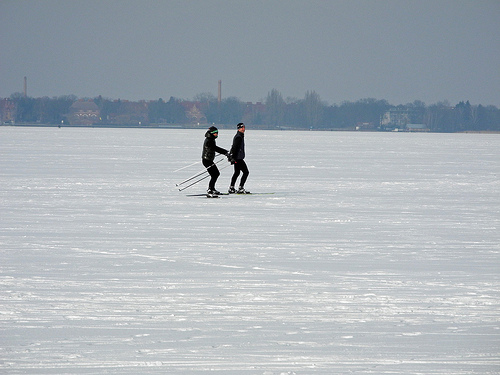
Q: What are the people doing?
A: Skiing.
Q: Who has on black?
A: People skiing.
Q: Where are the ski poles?
A: In people's hands.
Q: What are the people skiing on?
A: Snow.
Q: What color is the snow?
A: White.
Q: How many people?
A: Two.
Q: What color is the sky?
A: Gray.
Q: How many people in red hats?
A: None.